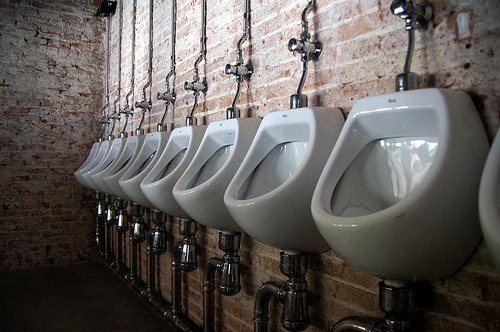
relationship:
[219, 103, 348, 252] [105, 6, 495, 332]
urinal on brick wall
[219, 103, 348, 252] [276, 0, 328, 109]
urinal has metal pipe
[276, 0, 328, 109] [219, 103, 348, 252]
metal pipe above urinal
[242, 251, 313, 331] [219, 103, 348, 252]
pipe below urinal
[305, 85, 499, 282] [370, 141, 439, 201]
urinal has reflection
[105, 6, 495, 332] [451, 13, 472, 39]
brick wall has white spot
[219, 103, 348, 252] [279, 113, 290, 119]
urinal has words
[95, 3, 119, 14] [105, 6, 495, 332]
object on brick wall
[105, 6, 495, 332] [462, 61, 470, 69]
brick wall has black spot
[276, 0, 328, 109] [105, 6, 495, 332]
metal pipe on brick wall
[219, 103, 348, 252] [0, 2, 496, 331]
urinal in men's room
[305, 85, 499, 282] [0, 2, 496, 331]
urinal in men's room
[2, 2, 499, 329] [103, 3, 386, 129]
photo has light